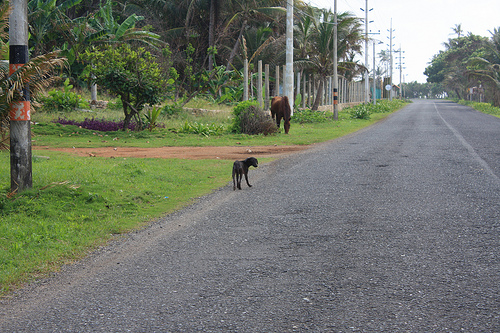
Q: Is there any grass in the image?
A: Yes, there is grass.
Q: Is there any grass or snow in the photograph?
A: Yes, there is grass.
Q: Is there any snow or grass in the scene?
A: Yes, there is grass.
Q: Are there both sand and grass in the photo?
A: No, there is grass but no sand.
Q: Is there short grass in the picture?
A: Yes, there is short grass.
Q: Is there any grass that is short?
A: Yes, there is grass that is short.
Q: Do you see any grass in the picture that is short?
A: Yes, there is grass that is short.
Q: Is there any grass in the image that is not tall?
A: Yes, there is short grass.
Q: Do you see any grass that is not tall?
A: Yes, there is short grass.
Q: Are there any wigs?
A: No, there are no wigs.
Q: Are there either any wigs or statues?
A: No, there are no wigs or statues.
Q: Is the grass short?
A: Yes, the grass is short.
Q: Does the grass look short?
A: Yes, the grass is short.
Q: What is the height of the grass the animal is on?
A: The grass is short.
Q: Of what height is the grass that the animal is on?
A: The grass is short.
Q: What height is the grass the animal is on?
A: The grass is short.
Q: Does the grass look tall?
A: No, the grass is short.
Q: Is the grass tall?
A: No, the grass is short.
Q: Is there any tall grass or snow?
A: No, there is grass but it is short.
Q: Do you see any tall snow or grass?
A: No, there is grass but it is short.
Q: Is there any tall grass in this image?
A: No, there is grass but it is short.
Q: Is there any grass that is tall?
A: No, there is grass but it is short.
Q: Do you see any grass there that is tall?
A: No, there is grass but it is short.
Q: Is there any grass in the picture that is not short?
A: No, there is grass but it is short.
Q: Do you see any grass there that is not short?
A: No, there is grass but it is short.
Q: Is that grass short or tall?
A: The grass is short.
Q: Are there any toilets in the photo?
A: No, there are no toilets.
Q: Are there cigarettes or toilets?
A: No, there are no toilets or cigarettes.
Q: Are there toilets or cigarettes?
A: No, there are no toilets or cigarettes.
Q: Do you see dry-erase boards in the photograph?
A: No, there are no dry-erase boards.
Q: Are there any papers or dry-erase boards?
A: No, there are no dry-erase boards or papers.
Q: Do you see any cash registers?
A: No, there are no cash registers.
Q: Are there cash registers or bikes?
A: No, there are no cash registers or bikes.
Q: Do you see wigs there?
A: No, there are no wigs.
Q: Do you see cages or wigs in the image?
A: No, there are no wigs or cages.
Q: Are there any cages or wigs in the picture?
A: No, there are no wigs or cages.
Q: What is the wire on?
A: The wire is on the utility pole.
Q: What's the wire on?
A: The wire is on the utility pole.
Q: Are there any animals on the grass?
A: Yes, there is an animal on the grass.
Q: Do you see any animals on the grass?
A: Yes, there is an animal on the grass.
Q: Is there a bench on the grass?
A: No, there is an animal on the grass.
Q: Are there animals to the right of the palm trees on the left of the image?
A: Yes, there is an animal to the right of the palms.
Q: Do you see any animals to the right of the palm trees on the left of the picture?
A: Yes, there is an animal to the right of the palms.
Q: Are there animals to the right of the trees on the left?
A: Yes, there is an animal to the right of the palms.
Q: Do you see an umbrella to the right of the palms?
A: No, there is an animal to the right of the palms.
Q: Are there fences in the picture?
A: Yes, there is a fence.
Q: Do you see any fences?
A: Yes, there is a fence.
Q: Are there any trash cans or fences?
A: Yes, there is a fence.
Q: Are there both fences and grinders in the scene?
A: No, there is a fence but no grinders.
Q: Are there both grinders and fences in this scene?
A: No, there is a fence but no grinders.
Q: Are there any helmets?
A: No, there are no helmets.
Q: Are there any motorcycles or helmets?
A: No, there are no helmets or motorcycles.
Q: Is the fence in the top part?
A: Yes, the fence is in the top of the image.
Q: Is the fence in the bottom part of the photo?
A: No, the fence is in the top of the image.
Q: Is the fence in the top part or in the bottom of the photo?
A: The fence is in the top of the image.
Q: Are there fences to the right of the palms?
A: Yes, there is a fence to the right of the palms.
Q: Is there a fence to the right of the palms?
A: Yes, there is a fence to the right of the palms.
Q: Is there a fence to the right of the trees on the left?
A: Yes, there is a fence to the right of the palms.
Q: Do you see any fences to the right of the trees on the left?
A: Yes, there is a fence to the right of the palms.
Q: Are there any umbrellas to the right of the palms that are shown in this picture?
A: No, there is a fence to the right of the palms.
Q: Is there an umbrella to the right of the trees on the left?
A: No, there is a fence to the right of the palms.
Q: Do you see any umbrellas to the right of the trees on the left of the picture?
A: No, there is a fence to the right of the palms.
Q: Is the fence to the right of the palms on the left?
A: Yes, the fence is to the right of the palm trees.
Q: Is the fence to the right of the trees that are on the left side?
A: Yes, the fence is to the right of the palm trees.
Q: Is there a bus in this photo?
A: No, there are no buses.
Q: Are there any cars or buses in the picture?
A: No, there are no buses or cars.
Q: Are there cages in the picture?
A: No, there are no cages.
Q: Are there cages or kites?
A: No, there are no cages or kites.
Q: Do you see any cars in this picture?
A: No, there are no cars.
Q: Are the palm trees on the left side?
A: Yes, the palm trees are on the left of the image.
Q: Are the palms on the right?
A: No, the palms are on the left of the image.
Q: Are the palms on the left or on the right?
A: The palms are on the left of the image.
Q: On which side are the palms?
A: The palms are on the left of the image.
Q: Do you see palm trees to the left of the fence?
A: Yes, there are palm trees to the left of the fence.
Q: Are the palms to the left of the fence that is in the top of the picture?
A: Yes, the palms are to the left of the fence.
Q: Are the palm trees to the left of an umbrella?
A: No, the palm trees are to the left of the fence.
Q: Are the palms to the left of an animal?
A: Yes, the palms are to the left of an animal.